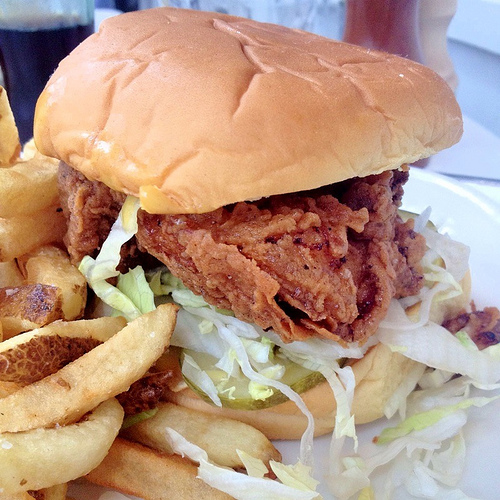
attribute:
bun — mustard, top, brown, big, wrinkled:
[52, 12, 460, 180]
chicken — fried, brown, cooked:
[52, 173, 427, 302]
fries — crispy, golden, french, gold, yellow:
[2, 102, 221, 498]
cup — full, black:
[2, 5, 89, 153]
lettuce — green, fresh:
[72, 199, 467, 402]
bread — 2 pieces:
[30, 6, 461, 204]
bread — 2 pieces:
[190, 239, 484, 439]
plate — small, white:
[416, 165, 484, 332]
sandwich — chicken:
[33, 5, 473, 443]